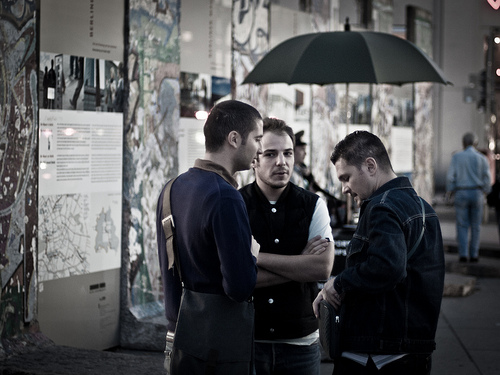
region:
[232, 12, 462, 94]
a black umbrella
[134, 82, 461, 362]
three men are talking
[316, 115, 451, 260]
men has short hair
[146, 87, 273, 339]
man wears a blue sweater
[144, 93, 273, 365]
man carries a black bag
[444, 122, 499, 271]
man wears blue clothes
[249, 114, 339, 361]
man with a black vest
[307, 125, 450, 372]
man wears a blue top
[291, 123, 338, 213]
a policeman behind a man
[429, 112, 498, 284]
person walking on the street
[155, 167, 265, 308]
a man wearing a blue shirt.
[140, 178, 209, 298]
A strap strapped on a man's shoulder.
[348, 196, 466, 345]
A man wearing a denim jacket.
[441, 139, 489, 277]
a man wearing all blue.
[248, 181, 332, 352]
A man wearing a black vest.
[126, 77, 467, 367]
Three man standing in front of a wall.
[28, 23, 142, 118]
Pictures dislayed on a wall.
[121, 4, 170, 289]
Paintings hanging on a wall.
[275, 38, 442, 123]
An umbrella standing on a table.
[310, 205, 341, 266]
A man wearing a white shirt under a vest.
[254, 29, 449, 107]
A plain black umbrella above the men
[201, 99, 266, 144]
Short black hair on the left man's head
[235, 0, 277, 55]
A panel of graffiti on the wall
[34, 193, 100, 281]
A white map on the wall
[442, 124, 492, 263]
A man dressed in blue on the sidewalk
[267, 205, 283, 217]
A small white button on the black vest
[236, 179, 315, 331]
A black vest on the center man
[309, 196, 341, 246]
A short white shirt on the center man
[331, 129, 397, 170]
Short brown hair on the man on the right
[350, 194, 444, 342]
A blue denim jacket on the right man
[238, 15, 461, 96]
a large black umbrella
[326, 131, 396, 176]
black short cut hair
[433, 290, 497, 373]
part of a sidewalk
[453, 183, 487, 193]
a man's belt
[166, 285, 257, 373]
a large black bag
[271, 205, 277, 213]
a white button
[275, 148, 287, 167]
the nose of a man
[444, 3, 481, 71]
part of a white wall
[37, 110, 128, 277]
a large white paper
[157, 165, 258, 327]
part of a man's blue sweater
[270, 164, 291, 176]
A thin mustache on the center man's lip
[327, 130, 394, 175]
Short brown hair on the right man's head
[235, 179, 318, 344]
A black vest on the man in the center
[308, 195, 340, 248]
A short sleeve white shirt on the center man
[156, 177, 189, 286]
A brown leather strap around the man's shoulder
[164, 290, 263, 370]
A dark leather bag carried by the left man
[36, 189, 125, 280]
A map of a train system on the wall